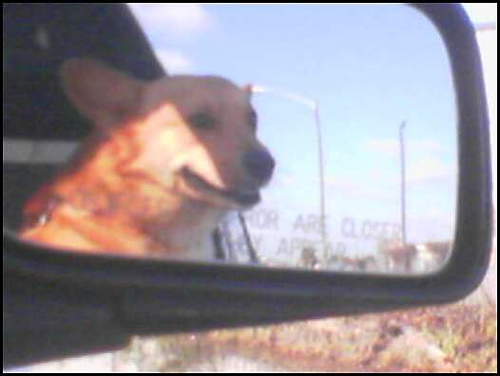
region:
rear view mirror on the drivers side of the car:
[5, 3, 459, 281]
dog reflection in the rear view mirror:
[18, 49, 283, 259]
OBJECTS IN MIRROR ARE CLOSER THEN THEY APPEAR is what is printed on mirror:
[58, 189, 414, 271]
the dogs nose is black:
[223, 143, 277, 187]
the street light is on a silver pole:
[244, 77, 344, 264]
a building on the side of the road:
[379, 228, 446, 276]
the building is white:
[374, 234, 449, 274]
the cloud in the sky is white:
[131, 3, 228, 38]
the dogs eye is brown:
[183, 105, 223, 142]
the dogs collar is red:
[58, 185, 193, 261]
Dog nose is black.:
[237, 143, 280, 183]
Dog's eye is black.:
[176, 95, 221, 142]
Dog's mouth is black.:
[173, 165, 249, 222]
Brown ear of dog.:
[46, 50, 143, 126]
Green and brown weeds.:
[323, 320, 492, 365]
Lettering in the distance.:
[253, 207, 407, 240]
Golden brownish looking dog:
[35, 55, 301, 250]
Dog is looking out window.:
[145, 67, 292, 237]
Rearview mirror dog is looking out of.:
[5, 6, 492, 331]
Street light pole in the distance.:
[383, 106, 428, 247]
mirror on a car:
[3, 2, 494, 322]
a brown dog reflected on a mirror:
[6, 37, 298, 258]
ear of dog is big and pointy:
[45, 46, 151, 141]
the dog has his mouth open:
[165, 135, 280, 215]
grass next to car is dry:
[231, 328, 493, 370]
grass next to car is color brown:
[246, 325, 496, 365]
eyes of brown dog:
[175, 102, 264, 133]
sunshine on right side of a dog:
[74, 90, 231, 264]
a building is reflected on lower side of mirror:
[374, 233, 458, 274]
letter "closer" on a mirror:
[334, 211, 414, 252]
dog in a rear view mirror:
[10, 49, 296, 267]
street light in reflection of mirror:
[252, 75, 359, 275]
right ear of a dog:
[44, 44, 149, 135]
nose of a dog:
[235, 144, 282, 186]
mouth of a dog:
[169, 165, 263, 217]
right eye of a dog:
[175, 102, 226, 137]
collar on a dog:
[18, 183, 155, 254]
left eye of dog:
[243, 102, 264, 132]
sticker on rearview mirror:
[211, 201, 413, 274]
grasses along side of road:
[259, 318, 491, 367]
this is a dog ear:
[53, 59, 152, 130]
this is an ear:
[233, 76, 263, 105]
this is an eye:
[241, 103, 263, 138]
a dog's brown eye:
[180, 99, 225, 141]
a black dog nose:
[231, 139, 284, 194]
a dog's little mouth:
[173, 153, 280, 229]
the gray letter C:
[336, 204, 353, 244]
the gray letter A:
[292, 208, 308, 237]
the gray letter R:
[301, 209, 323, 237]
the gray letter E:
[313, 210, 327, 235]